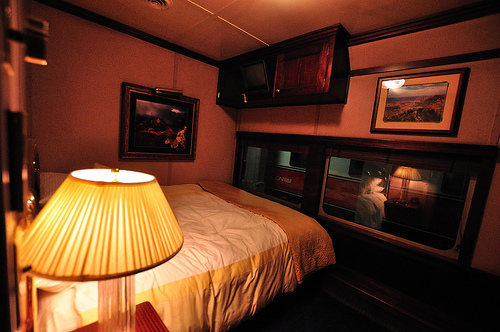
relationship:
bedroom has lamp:
[5, 2, 497, 328] [21, 165, 195, 331]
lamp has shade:
[21, 165, 195, 331] [22, 167, 181, 282]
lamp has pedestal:
[21, 165, 195, 331] [99, 273, 137, 330]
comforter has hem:
[29, 176, 334, 331] [53, 239, 301, 331]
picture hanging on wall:
[118, 80, 197, 164] [22, 2, 235, 186]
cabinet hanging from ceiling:
[214, 24, 349, 105] [72, 2, 496, 55]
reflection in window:
[356, 164, 453, 241] [321, 148, 470, 256]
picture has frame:
[118, 80, 197, 164] [120, 79, 198, 160]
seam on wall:
[166, 49, 178, 187] [22, 2, 235, 186]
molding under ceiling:
[50, 3, 223, 72] [72, 2, 496, 55]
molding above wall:
[50, 3, 223, 72] [22, 2, 235, 186]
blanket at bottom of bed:
[198, 178, 336, 285] [15, 139, 335, 329]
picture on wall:
[118, 80, 197, 164] [22, 2, 235, 186]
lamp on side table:
[21, 165, 195, 331] [70, 303, 167, 332]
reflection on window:
[356, 164, 453, 241] [321, 148, 470, 256]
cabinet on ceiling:
[214, 24, 349, 105] [72, 2, 496, 55]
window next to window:
[321, 148, 470, 256] [236, 133, 311, 203]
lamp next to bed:
[21, 165, 195, 331] [15, 139, 335, 329]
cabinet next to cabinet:
[214, 24, 349, 105] [214, 24, 349, 105]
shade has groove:
[22, 167, 181, 282] [115, 184, 132, 269]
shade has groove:
[22, 167, 181, 282] [60, 186, 130, 270]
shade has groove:
[22, 167, 181, 282] [78, 180, 96, 277]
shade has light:
[22, 167, 181, 282] [79, 172, 148, 183]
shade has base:
[22, 167, 181, 282] [16, 236, 190, 283]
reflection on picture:
[377, 76, 409, 92] [372, 72, 473, 139]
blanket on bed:
[198, 178, 336, 285] [15, 139, 335, 329]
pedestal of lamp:
[99, 273, 137, 330] [21, 165, 195, 331]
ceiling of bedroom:
[72, 2, 496, 55] [5, 2, 497, 328]